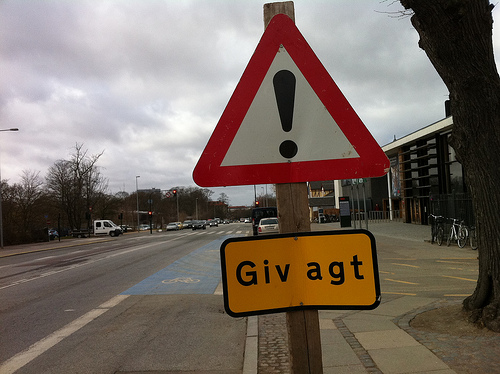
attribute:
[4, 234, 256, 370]
road — blue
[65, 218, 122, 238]
truck — white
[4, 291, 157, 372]
line — white